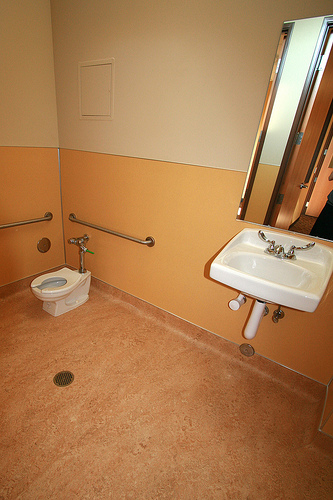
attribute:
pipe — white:
[242, 297, 269, 341]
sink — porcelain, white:
[208, 227, 332, 313]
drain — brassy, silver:
[52, 370, 75, 388]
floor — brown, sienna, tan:
[0, 280, 332, 500]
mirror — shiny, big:
[236, 14, 332, 242]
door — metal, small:
[268, 26, 333, 230]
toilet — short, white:
[30, 267, 91, 318]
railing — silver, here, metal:
[67, 212, 155, 248]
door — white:
[79, 63, 113, 117]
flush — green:
[84, 248, 94, 256]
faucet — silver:
[274, 245, 296, 261]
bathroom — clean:
[0, 0, 332, 499]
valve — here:
[271, 310, 285, 325]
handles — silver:
[289, 242, 315, 259]